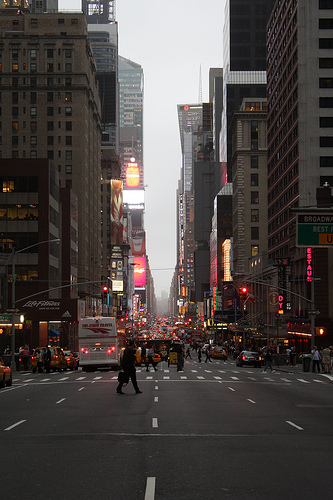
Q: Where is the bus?
A: On the street.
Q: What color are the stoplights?
A: Red.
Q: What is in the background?
A: Buildings.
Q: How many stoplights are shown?
A: Two.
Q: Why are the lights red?
A: To alert traffic to stop.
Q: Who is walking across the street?
A: The person.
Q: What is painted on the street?
A: White lines.